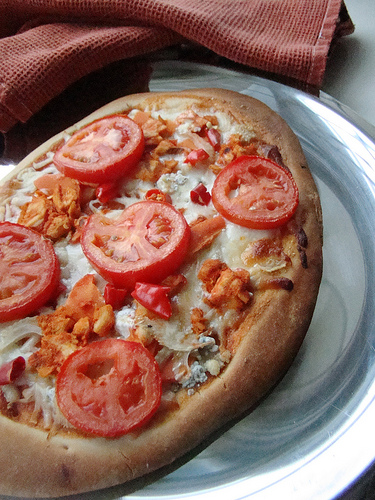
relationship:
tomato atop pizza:
[56, 339, 162, 438] [1, 80, 340, 493]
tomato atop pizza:
[81, 200, 192, 288] [1, 80, 340, 493]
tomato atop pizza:
[0, 215, 63, 323] [1, 80, 340, 493]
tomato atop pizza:
[82, 200, 195, 283] [1, 80, 340, 493]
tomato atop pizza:
[52, 115, 144, 185] [1, 80, 340, 493]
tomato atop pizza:
[213, 151, 301, 230] [1, 80, 340, 493]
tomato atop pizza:
[49, 111, 145, 184] [1, 80, 340, 493]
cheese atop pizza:
[2, 99, 279, 433] [3, 202, 239, 458]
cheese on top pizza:
[2, 99, 279, 433] [1, 80, 340, 493]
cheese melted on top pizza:
[2, 105, 285, 431] [1, 80, 340, 493]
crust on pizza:
[0, 87, 323, 500] [1, 80, 340, 493]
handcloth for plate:
[0, 1, 345, 117] [201, 63, 374, 498]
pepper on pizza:
[102, 277, 179, 323] [1, 80, 340, 493]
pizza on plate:
[1, 80, 340, 493] [108, 61, 373, 499]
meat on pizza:
[28, 284, 122, 383] [1, 80, 340, 493]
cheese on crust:
[2, 99, 279, 433] [1, 406, 216, 498]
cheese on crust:
[2, 99, 279, 433] [176, 323, 307, 464]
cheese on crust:
[2, 99, 279, 433] [241, 100, 329, 386]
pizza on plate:
[1, 80, 340, 493] [0, 59, 375, 498]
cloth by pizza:
[0, 0, 356, 134] [1, 80, 340, 493]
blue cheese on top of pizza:
[178, 313, 205, 416] [72, 130, 196, 270]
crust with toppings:
[224, 93, 284, 135] [6, 109, 306, 438]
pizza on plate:
[1, 87, 325, 500] [0, 59, 375, 500]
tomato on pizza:
[0, 221, 61, 324] [22, 94, 334, 393]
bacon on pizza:
[25, 271, 116, 378] [1, 80, 340, 493]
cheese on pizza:
[2, 99, 279, 433] [0, 69, 331, 358]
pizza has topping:
[1, 87, 325, 500] [139, 106, 168, 144]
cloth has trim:
[2, 0, 355, 121] [303, 1, 340, 88]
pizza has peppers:
[1, 80, 340, 493] [194, 179, 215, 212]